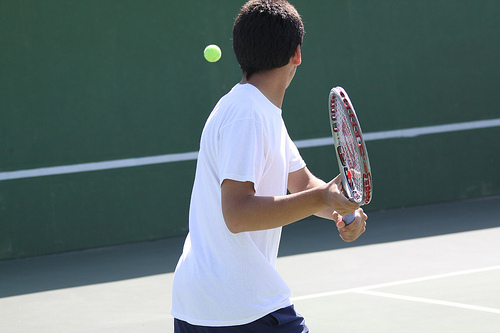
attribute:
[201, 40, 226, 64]
tennis ball — small, green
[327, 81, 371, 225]
tennis racket — here, white, red, gre, silver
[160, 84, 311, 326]
t shirt — white, ice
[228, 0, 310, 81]
head — man's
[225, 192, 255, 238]
elbow — here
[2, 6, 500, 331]
tennis court — complete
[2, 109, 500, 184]
line — white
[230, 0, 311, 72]
hair — short, black, dark brown, dark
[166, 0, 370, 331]
man — young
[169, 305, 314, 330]
shorts — blue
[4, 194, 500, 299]
shadow — wall's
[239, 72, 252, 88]
hair — short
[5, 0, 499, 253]
wall — large, green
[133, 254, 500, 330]
lines — white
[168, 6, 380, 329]
boy — young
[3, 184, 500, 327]
tennis field — marked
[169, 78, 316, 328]
tee shirt — white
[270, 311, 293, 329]
pants — blue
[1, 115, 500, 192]
stripe — white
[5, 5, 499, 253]
background — green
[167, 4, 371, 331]
tennis player — swinging, standing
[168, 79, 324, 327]
shirt — white